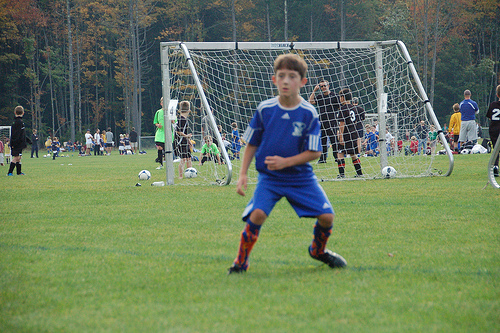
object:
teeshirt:
[242, 96, 324, 178]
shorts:
[240, 176, 335, 221]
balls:
[135, 169, 151, 182]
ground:
[119, 172, 213, 227]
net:
[170, 55, 236, 127]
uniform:
[10, 117, 28, 156]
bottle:
[151, 181, 165, 187]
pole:
[403, 46, 455, 177]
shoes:
[227, 244, 347, 277]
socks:
[7, 161, 21, 174]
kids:
[153, 96, 178, 166]